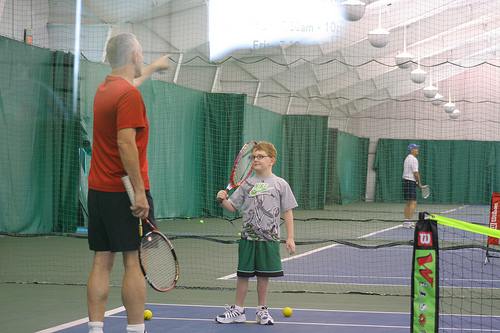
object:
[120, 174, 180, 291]
racket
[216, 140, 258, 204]
racket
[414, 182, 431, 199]
racket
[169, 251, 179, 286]
edge